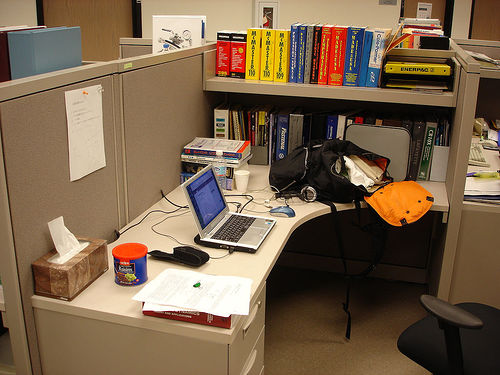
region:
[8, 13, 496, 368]
Cluttered office cubicle space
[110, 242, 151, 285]
Package of canned food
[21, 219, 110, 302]
Brown box of Kleenex facial tissue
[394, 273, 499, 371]
Empty black office chair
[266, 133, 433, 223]
Opened black bag with orange flap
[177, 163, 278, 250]
Opened laptop with screen lit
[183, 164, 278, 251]
Laptop sitting on desk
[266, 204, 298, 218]
Blue and silver computer mouse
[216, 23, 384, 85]
Books sitting on shelf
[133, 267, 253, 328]
Papers and book on desk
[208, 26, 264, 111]
two red and black books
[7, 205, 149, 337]
a box of tissues on a desk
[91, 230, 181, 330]
a blue and orange container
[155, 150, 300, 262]
a silver and black laptop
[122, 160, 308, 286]
a laptop on a desk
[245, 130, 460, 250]
a brown and orange backpack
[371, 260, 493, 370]
a black computer chair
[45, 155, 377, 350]
a white computer desk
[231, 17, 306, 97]
three yellow books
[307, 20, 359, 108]
two yellow and red books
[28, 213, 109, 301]
A box of tissue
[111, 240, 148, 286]
A blue can with an orange cap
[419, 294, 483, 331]
Armrest of a desk chair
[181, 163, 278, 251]
Silver laptop with black keys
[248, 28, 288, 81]
Spines of three books in a row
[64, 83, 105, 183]
Piece of paper tacked to a board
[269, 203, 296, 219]
A blue mouse on a desk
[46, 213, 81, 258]
Tissue rising out of it's box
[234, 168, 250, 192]
A small, white plastic cup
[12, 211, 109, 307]
tissue box on the desk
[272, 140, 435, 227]
back pack open on the desk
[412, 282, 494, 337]
arm of the chair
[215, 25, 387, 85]
books on the shelf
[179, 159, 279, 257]
laptop on the desk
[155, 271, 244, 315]
papers on top of the book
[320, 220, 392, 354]
strap of the backpack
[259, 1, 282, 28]
picture on the wall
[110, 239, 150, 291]
can on the desk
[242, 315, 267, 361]
drawers on the desk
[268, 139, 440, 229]
an open black bag on a desk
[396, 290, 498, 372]
a black desk chair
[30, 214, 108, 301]
a box of tissue on a desk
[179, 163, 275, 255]
an open laptop on a desk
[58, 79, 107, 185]
a paper pinned to a cubicle divider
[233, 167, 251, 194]
a white cup on a desk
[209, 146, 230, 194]
a water bottle on a desk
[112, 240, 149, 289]
a can of nuts on a desk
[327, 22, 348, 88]
a red book on a desk shelf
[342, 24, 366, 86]
a blue book on a desk shelf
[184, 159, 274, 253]
laptop on top of office desk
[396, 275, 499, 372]
chair near office desk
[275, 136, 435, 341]
backpack on top of office desk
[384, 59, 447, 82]
binder on top of office desk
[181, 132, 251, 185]
stack of books on top of office desk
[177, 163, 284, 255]
Laptop is turned on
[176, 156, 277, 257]
Laptop is turned on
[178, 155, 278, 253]
Laptop is turned on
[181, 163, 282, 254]
Laptop is turned on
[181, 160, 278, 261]
Laptop is turned on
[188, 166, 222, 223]
Screen of a laptop